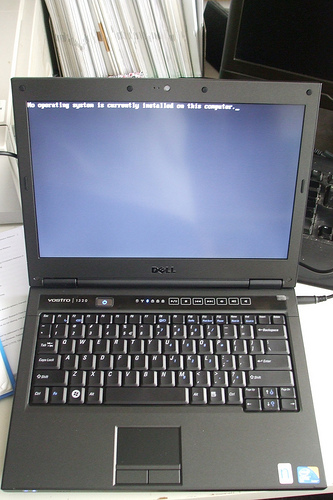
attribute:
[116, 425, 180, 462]
mousepad — small, black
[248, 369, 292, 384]
key — shift, computer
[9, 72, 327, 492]
computer — laptop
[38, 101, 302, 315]
monitor — display, computer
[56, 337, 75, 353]
key — Q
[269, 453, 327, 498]
sticker — corporate, intel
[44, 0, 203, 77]
booklets — paper, white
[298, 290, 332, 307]
plug — black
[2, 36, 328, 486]
laptop — small, black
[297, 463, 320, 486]
windows symbol — small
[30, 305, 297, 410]
keyboard — black, computer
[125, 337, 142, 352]
key — T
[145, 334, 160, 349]
key — Y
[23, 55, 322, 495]
key — computer, windows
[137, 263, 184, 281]
logo — dell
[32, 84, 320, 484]
computer — black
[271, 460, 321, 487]
stickers — logo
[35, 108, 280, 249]
screen — blue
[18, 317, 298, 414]
keyboard — laptop